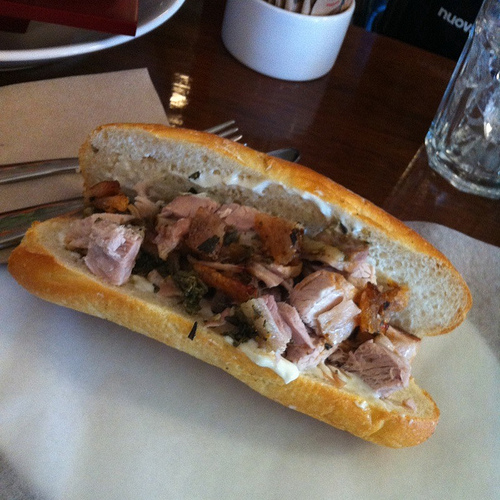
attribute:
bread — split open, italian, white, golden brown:
[6, 117, 481, 453]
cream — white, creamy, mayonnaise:
[102, 158, 362, 237]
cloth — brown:
[0, 62, 186, 224]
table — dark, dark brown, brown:
[5, 3, 498, 498]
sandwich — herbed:
[3, 117, 477, 459]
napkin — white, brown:
[4, 214, 498, 498]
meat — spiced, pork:
[70, 195, 418, 396]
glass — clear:
[419, 1, 500, 199]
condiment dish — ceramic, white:
[217, 1, 362, 85]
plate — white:
[1, 1, 196, 72]